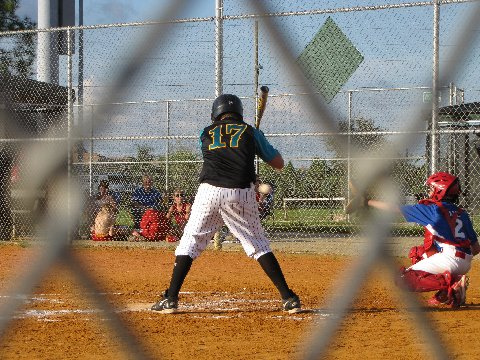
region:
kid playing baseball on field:
[127, 70, 295, 322]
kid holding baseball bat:
[141, 81, 303, 321]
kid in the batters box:
[119, 66, 307, 332]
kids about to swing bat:
[146, 45, 298, 322]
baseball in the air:
[255, 181, 281, 199]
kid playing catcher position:
[321, 154, 471, 311]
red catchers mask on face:
[406, 159, 475, 209]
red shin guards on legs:
[384, 261, 469, 309]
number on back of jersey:
[205, 118, 250, 152]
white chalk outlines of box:
[2, 279, 279, 335]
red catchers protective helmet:
[424, 158, 472, 211]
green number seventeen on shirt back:
[208, 119, 251, 150]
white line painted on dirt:
[35, 287, 112, 334]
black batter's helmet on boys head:
[206, 88, 249, 118]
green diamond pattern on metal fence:
[289, 21, 373, 101]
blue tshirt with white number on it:
[407, 195, 478, 241]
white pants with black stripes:
[166, 179, 295, 244]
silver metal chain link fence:
[79, 32, 201, 87]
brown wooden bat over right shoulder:
[256, 75, 275, 129]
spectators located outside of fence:
[95, 166, 180, 240]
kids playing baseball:
[65, 26, 475, 348]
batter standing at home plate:
[158, 81, 319, 330]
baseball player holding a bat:
[150, 71, 321, 324]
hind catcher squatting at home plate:
[351, 136, 475, 325]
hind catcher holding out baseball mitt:
[331, 132, 478, 324]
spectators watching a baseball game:
[77, 155, 194, 241]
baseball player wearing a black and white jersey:
[148, 68, 333, 342]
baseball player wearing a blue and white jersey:
[333, 138, 475, 313]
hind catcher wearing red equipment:
[341, 154, 478, 319]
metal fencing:
[10, 70, 106, 342]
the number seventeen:
[205, 117, 253, 152]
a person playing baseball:
[146, 85, 306, 323]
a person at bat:
[182, 82, 307, 315]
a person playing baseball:
[407, 163, 469, 301]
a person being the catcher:
[393, 166, 477, 311]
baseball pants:
[177, 172, 272, 267]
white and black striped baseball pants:
[176, 175, 273, 257]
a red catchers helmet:
[419, 169, 458, 202]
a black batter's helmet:
[204, 89, 254, 119]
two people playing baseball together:
[151, 82, 475, 310]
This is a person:
[143, 70, 307, 338]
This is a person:
[398, 150, 477, 332]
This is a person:
[88, 161, 120, 242]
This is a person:
[122, 161, 163, 241]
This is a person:
[170, 173, 196, 237]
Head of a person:
[201, 78, 257, 132]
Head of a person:
[411, 150, 474, 207]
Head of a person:
[95, 168, 120, 198]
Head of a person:
[141, 170, 159, 195]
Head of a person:
[167, 179, 188, 207]